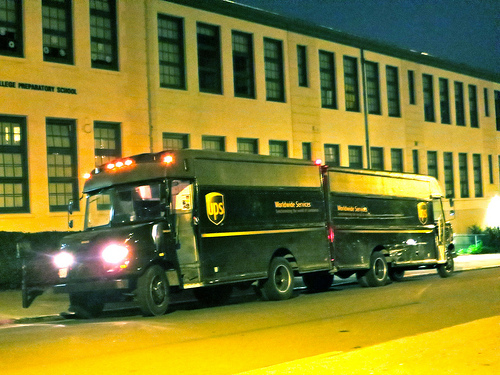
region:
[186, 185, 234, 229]
The truck has a UPS symbol on it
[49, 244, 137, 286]
The lights are on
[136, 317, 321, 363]
The road is lit up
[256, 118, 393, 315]
Two trucks are back to back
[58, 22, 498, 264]
The building has many windows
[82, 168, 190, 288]
No one is in the truck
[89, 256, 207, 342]
The wheels are black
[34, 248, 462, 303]
The trucks are parked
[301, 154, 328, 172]
The light is red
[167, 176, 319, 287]
The trucks are dark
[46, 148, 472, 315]
two back to back delivery trucks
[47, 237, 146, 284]
bright headlights on a delivery truck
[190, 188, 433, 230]
yellow logos and lettering on the side of two trucks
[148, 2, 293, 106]
windows in the side of a large building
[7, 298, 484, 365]
yellow light reflected on the pavement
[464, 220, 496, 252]
bushes at the side of a street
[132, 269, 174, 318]
front left wheel of a delivery truck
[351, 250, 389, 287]
rear right wheel of a delivery truck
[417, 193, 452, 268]
door of a delivery truck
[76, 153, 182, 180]
orange lights at the top of the front of a truck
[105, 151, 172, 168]
Bright orange lights on front of truck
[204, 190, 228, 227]
Yellow logo on black truck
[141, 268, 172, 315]
Black tire on truck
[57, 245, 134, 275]
Bright headlights on front of truck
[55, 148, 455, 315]
Two black trucks on street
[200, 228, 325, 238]
Yellow stripe on side of truck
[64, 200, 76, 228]
Silver side mirror on truck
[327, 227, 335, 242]
Red tail light on back of truck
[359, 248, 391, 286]
Black rear tire on truck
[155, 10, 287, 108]
Row of windows on tan building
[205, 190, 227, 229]
A UPS sign on a truck.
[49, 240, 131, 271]
A pair of head lights.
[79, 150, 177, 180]
Lights on a truck.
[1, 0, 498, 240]
A building with windows.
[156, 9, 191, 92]
A window on a building.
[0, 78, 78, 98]
A sign of a school.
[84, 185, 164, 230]
A front window of a truck.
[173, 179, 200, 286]
A door of a truck.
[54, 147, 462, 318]
Two UPS trucks on a street.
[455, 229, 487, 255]
A fence.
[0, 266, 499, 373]
urban street at night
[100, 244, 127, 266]
lit headlight on a UPS truck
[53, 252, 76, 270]
lit headlight on a UPS truck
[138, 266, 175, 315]
tire on a parked UPS truck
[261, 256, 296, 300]
tire on a parked UPS truck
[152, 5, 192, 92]
upper window in a large city school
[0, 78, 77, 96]
name of the school written in black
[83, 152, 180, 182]
row of small lights near the top of a UPS truck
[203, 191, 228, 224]
black and yellow shield on the side up a UPS truck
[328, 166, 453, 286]
UPS truck parked in front of a school